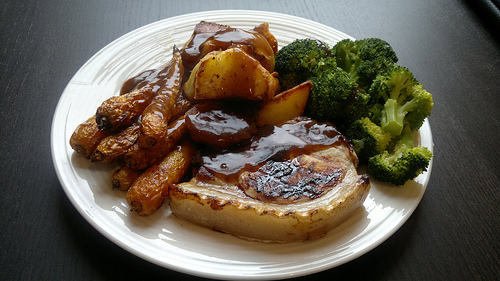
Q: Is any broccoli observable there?
A: Yes, there is broccoli.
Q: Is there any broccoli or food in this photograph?
A: Yes, there is broccoli.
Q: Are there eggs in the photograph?
A: No, there are no eggs.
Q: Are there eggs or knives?
A: No, there are no eggs or knives.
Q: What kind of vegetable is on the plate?
A: The vegetable is broccoli.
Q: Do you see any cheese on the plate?
A: No, there is broccoli on the plate.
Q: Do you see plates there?
A: Yes, there is a plate.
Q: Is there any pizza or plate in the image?
A: Yes, there is a plate.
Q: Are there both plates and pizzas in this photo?
A: No, there is a plate but no pizzas.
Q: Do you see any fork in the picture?
A: No, there are no forks.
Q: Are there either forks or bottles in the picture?
A: No, there are no forks or bottles.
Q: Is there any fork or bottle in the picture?
A: No, there are no forks or bottles.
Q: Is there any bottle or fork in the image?
A: No, there are no forks or bottles.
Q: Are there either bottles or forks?
A: No, there are no forks or bottles.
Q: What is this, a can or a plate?
A: This is a plate.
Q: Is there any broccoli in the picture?
A: Yes, there is broccoli.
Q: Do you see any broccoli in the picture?
A: Yes, there is broccoli.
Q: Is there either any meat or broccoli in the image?
A: Yes, there is broccoli.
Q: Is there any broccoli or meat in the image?
A: Yes, there is broccoli.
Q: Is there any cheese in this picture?
A: No, there is no cheese.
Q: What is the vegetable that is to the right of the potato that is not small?
A: The vegetable is broccoli.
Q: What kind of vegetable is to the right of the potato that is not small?
A: The vegetable is broccoli.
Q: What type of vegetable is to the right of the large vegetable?
A: The vegetable is broccoli.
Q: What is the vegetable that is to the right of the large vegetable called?
A: The vegetable is broccoli.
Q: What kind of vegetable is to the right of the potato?
A: The vegetable is broccoli.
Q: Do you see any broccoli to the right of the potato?
A: Yes, there is broccoli to the right of the potato.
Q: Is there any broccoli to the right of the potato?
A: Yes, there is broccoli to the right of the potato.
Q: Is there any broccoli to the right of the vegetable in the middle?
A: Yes, there is broccoli to the right of the potato.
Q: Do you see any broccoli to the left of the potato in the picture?
A: No, the broccoli is to the right of the potato.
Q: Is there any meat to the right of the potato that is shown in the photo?
A: No, there is broccoli to the right of the potato.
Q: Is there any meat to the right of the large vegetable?
A: No, there is broccoli to the right of the potato.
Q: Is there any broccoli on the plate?
A: Yes, there is broccoli on the plate.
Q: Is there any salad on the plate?
A: No, there is broccoli on the plate.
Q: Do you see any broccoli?
A: Yes, there is broccoli.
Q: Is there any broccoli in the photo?
A: Yes, there is broccoli.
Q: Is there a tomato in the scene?
A: No, there are no tomatoes.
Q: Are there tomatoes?
A: No, there are no tomatoes.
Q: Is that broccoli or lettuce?
A: That is broccoli.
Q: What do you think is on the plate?
A: The broccoli is on the plate.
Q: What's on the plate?
A: The broccoli is on the plate.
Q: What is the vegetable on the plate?
A: The vegetable is broccoli.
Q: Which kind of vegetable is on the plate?
A: The vegetable is broccoli.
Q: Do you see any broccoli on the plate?
A: Yes, there is broccoli on the plate.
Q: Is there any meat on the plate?
A: No, there is broccoli on the plate.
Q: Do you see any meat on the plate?
A: No, there is broccoli on the plate.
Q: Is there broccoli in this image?
A: Yes, there is broccoli.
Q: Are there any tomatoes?
A: No, there are no tomatoes.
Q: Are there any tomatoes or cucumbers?
A: No, there are no tomatoes or cucumbers.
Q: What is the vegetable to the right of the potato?
A: The vegetable is broccoli.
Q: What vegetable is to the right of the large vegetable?
A: The vegetable is broccoli.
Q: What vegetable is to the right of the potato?
A: The vegetable is broccoli.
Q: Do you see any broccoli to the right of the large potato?
A: Yes, there is broccoli to the right of the potato.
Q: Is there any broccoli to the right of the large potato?
A: Yes, there is broccoli to the right of the potato.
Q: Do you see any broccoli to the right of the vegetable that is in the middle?
A: Yes, there is broccoli to the right of the potato.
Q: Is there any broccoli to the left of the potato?
A: No, the broccoli is to the right of the potato.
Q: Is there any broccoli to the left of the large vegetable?
A: No, the broccoli is to the right of the potato.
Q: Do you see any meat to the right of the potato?
A: No, there is broccoli to the right of the potato.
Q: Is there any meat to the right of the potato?
A: No, there is broccoli to the right of the potato.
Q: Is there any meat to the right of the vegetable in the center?
A: No, there is broccoli to the right of the potato.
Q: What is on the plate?
A: The broccoli is on the plate.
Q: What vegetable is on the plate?
A: The vegetable is broccoli.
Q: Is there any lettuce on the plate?
A: No, there is broccoli on the plate.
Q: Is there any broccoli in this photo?
A: Yes, there is broccoli.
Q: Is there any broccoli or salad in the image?
A: Yes, there is broccoli.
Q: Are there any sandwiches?
A: No, there are no sandwiches.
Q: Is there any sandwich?
A: No, there are no sandwiches.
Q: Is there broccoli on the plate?
A: Yes, there is broccoli on the plate.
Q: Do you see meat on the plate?
A: No, there is broccoli on the plate.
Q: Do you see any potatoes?
A: Yes, there is a potato.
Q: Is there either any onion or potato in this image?
A: Yes, there is a potato.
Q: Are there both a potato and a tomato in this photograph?
A: No, there is a potato but no tomatoes.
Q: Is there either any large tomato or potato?
A: Yes, there is a large potato.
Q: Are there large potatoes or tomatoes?
A: Yes, there is a large potato.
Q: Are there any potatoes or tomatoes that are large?
A: Yes, the potato is large.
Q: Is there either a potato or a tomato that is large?
A: Yes, the potato is large.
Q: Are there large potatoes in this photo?
A: Yes, there is a large potato.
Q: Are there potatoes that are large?
A: Yes, there is a potato that is large.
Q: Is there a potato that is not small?
A: Yes, there is a large potato.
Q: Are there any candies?
A: No, there are no candies.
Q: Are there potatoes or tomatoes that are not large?
A: No, there is a potato but it is large.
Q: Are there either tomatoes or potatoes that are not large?
A: No, there is a potato but it is large.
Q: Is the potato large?
A: Yes, the potato is large.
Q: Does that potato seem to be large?
A: Yes, the potato is large.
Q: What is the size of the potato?
A: The potato is large.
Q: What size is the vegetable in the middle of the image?
A: The potato is large.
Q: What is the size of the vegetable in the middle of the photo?
A: The potato is large.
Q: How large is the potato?
A: The potato is large.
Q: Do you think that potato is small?
A: No, the potato is large.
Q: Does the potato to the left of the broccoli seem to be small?
A: No, the potato is large.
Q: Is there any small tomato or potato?
A: No, there is a potato but it is large.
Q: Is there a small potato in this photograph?
A: No, there is a potato but it is large.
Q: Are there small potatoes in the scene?
A: No, there is a potato but it is large.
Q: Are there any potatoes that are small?
A: No, there is a potato but it is large.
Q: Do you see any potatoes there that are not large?
A: No, there is a potato but it is large.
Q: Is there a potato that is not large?
A: No, there is a potato but it is large.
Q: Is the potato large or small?
A: The potato is large.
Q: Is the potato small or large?
A: The potato is large.